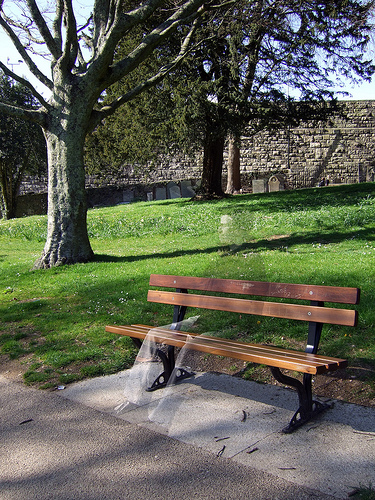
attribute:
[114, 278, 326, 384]
bench — brown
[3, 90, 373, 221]
wall — brick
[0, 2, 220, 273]
tree — tall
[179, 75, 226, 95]
leaves — green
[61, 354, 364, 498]
pavement — white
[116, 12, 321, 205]
tree — large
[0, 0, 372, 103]
sky — cloudy ,  blue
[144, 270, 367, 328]
bench back — wooden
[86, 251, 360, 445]
park bench — wooden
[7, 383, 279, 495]
path — gravel filled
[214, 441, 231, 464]
debris — piece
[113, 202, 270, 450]
man — transparent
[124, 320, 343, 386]
seat — wood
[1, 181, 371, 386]
grass — green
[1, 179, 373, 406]
grass — bright green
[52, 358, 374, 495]
slab — cement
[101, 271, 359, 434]
bench — wooden, metal, wood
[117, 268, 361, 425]
bench — metal, one, black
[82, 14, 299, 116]
branches — bare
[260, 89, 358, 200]
building — tall ,  gray , brick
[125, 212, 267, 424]
man — faded image 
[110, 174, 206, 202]
headstones — against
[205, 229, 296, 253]
dirt — small patch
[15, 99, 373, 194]
stone wall — gray, sunlit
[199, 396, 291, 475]
sticks — small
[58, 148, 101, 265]
trunk — sunlit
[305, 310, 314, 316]
screw — silver 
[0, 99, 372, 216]
wall — stoned